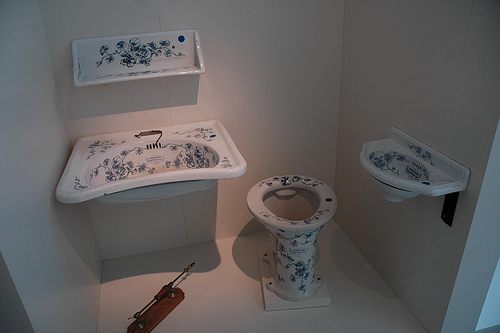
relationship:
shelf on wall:
[57, 20, 210, 103] [40, 0, 345, 262]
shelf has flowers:
[57, 20, 210, 103] [90, 35, 191, 75]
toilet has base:
[237, 165, 350, 316] [254, 238, 338, 314]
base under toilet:
[254, 238, 338, 314] [237, 165, 350, 316]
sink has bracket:
[355, 113, 477, 220] [435, 186, 468, 228]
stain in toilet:
[272, 201, 315, 224] [237, 165, 350, 316]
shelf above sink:
[57, 20, 210, 103] [43, 106, 249, 220]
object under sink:
[105, 257, 206, 333] [43, 106, 249, 220]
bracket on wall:
[435, 186, 468, 228] [327, 0, 499, 333]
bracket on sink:
[435, 186, 468, 228] [355, 113, 477, 220]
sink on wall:
[355, 113, 477, 220] [327, 0, 499, 333]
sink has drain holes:
[355, 113, 477, 220] [409, 159, 425, 174]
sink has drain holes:
[43, 106, 249, 220] [139, 139, 168, 154]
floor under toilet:
[93, 212, 428, 330] [237, 165, 350, 316]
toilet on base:
[237, 165, 350, 316] [254, 238, 338, 314]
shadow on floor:
[231, 215, 321, 281] [93, 212, 428, 330]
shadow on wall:
[231, 215, 321, 281] [40, 0, 345, 262]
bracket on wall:
[441, 192, 460, 228] [422, 196, 472, 238]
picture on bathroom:
[88, 31, 192, 72] [47, 33, 467, 290]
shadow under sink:
[231, 215, 321, 281] [56, 138, 244, 197]